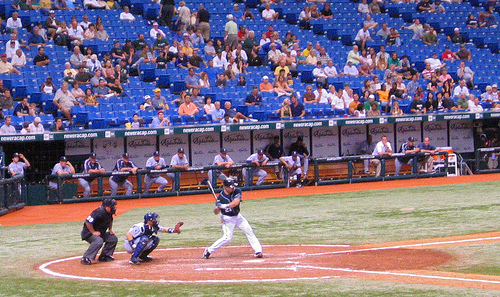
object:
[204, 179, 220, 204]
bat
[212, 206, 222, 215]
hand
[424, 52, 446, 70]
man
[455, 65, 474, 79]
shirt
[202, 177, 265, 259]
player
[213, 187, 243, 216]
shirt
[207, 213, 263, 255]
pants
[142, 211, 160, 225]
helmet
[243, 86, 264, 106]
baseball fan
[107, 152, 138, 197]
baseball players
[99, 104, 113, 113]
empty chairs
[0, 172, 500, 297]
baseball field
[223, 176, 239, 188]
baseball helmet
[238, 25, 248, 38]
man wearing red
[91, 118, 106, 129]
blue chairs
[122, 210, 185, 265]
baseball player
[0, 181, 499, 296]
green grass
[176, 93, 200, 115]
people watching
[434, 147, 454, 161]
orange cooler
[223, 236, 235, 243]
knee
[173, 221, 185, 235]
glove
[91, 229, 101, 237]
hand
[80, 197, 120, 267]
umpire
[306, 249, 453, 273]
pitch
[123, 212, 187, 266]
wearing shin guards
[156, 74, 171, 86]
seat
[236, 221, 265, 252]
man's leg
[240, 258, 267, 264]
base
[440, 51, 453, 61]
male in red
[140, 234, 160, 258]
leg pad